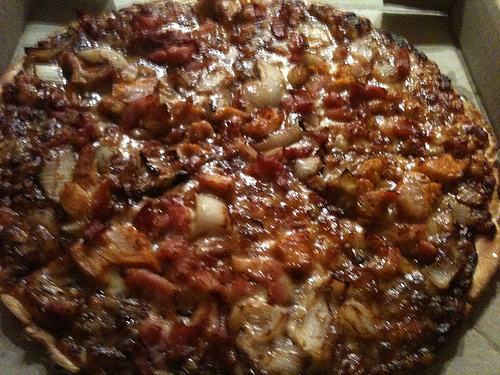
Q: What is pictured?
A: Pizza.